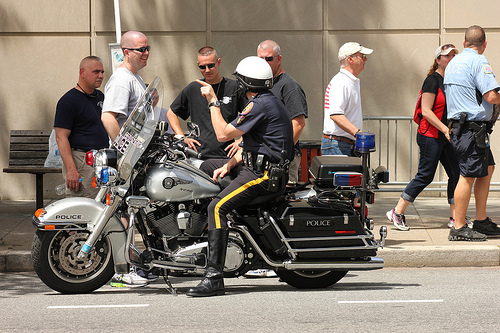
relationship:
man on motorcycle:
[186, 55, 298, 298] [27, 79, 383, 291]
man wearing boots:
[186, 55, 298, 298] [185, 225, 230, 297]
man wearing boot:
[186, 55, 298, 298] [190, 230, 228, 299]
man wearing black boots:
[186, 55, 298, 298] [182, 226, 232, 298]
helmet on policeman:
[234, 58, 274, 90] [189, 51, 292, 296]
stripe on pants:
[208, 173, 280, 231] [191, 157, 305, 272]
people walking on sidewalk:
[387, 45, 459, 230] [0, 196, 499, 272]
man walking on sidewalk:
[443, 24, 498, 240] [0, 196, 499, 272]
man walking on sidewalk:
[318, 37, 375, 160] [0, 196, 499, 272]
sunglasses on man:
[127, 46, 147, 53] [98, 31, 170, 285]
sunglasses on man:
[196, 60, 216, 70] [161, 48, 250, 158]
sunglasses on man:
[263, 57, 277, 64] [243, 39, 306, 149]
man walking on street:
[318, 37, 375, 160] [0, 200, 497, 330]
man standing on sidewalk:
[169, 45, 234, 155] [373, 197, 498, 239]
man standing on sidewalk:
[101, 28, 151, 149] [0, 196, 499, 272]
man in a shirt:
[54, 55, 110, 196] [53, 87, 109, 151]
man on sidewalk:
[186, 55, 298, 298] [0, 196, 499, 272]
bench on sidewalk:
[3, 128, 63, 209] [0, 196, 499, 272]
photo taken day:
[0, 8, 482, 324] [7, 4, 498, 330]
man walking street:
[443, 20, 483, 240] [375, 232, 484, 320]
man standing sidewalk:
[214, 47, 325, 182] [371, 220, 483, 259]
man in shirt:
[169, 45, 234, 155] [171, 77, 246, 162]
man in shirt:
[318, 37, 375, 160] [321, 66, 366, 143]